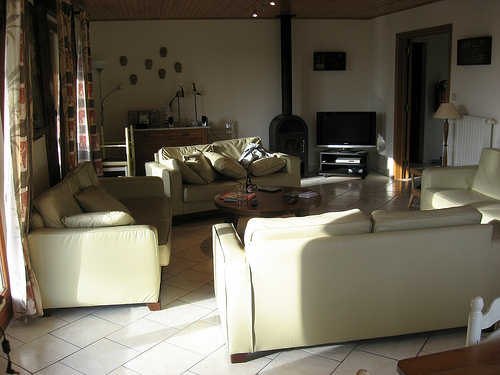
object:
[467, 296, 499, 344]
chair back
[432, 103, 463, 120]
lampshade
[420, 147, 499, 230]
couch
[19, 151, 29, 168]
flower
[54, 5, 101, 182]
curtain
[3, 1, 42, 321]
curtain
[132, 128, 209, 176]
cabinet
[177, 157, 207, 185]
cushion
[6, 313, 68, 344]
tiles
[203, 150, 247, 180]
pillows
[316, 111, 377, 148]
television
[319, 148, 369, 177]
stand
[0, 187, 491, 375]
floor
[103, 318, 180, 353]
tile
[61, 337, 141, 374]
tile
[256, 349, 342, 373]
tile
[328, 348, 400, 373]
tile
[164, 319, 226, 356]
tile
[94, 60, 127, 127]
lamp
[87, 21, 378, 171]
wall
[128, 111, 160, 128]
stereo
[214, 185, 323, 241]
wooden table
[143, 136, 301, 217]
sofa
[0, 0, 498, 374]
room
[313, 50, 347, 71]
frames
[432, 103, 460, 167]
lamp